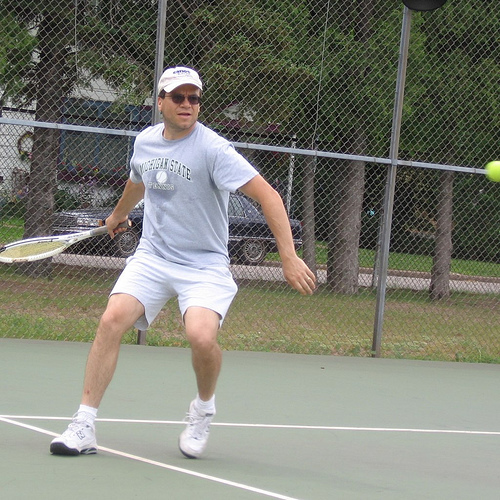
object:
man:
[49, 65, 317, 461]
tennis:
[2, 128, 499, 305]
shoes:
[178, 399, 216, 460]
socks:
[76, 404, 98, 425]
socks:
[194, 392, 216, 413]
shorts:
[106, 249, 238, 331]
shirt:
[129, 120, 260, 270]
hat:
[157, 65, 204, 96]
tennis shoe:
[49, 417, 99, 457]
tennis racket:
[0, 219, 133, 264]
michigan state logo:
[139, 157, 193, 192]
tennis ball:
[484, 161, 500, 183]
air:
[312, 117, 437, 219]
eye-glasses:
[164, 95, 203, 105]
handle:
[90, 219, 133, 238]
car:
[47, 192, 302, 266]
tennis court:
[0, 1, 499, 499]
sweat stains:
[146, 171, 178, 226]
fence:
[0, 0, 499, 364]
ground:
[0, 217, 499, 498]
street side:
[0, 263, 499, 315]